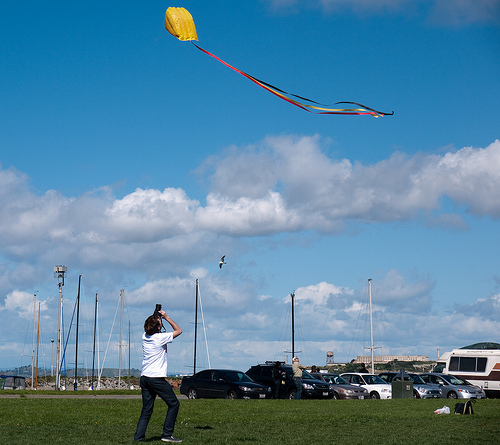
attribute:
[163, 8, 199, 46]
kite — flying, airborne, yellow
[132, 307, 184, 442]
man — photographing, looking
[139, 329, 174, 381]
shirt — white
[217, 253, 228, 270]
gull — airborne, flying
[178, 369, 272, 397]
car — parked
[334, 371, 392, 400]
car — white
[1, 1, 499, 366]
sky — blue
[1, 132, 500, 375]
clouds — white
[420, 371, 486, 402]
car — parked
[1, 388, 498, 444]
ground — grassy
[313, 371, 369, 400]
car — parked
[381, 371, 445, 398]
car — parked